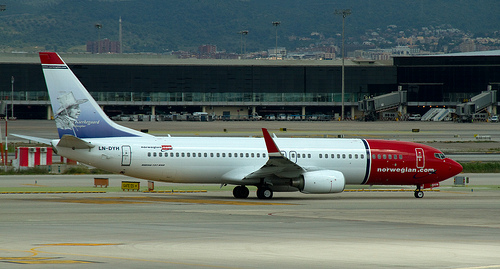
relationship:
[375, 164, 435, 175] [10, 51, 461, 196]
logo on plane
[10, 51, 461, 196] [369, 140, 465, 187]
plane has front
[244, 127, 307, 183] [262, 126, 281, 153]
wing has tip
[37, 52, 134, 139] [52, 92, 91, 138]
tip has portrait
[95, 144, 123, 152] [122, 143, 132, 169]
letters are next to door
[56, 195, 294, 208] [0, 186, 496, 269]
lines are painted on concrete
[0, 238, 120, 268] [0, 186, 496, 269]
lines are painted on concrete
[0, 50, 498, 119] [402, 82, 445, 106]
terminal has gates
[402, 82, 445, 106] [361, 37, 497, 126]
gates are in background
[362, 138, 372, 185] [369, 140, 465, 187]
stripe between front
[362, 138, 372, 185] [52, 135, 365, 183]
stripe between sections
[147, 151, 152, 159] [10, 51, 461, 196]
window on plane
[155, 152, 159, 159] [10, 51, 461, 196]
window on plane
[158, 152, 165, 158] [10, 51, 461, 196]
window on plane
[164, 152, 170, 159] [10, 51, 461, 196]
window on plane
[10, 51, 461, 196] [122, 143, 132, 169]
plane has door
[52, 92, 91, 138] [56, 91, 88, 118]
woman has hat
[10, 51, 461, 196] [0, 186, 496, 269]
plane sitting o runway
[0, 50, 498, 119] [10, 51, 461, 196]
terminal behind plane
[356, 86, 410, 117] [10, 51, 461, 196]
jetway behind plane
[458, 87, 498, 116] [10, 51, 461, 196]
jetway behind plane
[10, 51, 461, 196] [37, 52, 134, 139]
plane has tail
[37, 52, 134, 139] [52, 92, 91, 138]
tail has portrait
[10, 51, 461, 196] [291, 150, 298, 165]
plane has door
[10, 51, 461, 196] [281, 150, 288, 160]
plane has door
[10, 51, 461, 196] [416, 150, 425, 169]
plane has door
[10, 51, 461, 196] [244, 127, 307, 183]
plane has wing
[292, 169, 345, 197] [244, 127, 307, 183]
engine beside wing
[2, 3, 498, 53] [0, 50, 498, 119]
hill behind terminal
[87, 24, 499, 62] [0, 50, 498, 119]
city behind terminal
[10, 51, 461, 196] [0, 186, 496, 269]
plane standing on concrete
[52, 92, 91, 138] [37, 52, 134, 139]
portrait painted on tip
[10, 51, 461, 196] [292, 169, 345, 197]
plane has engine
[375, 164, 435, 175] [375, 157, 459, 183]
logo wrote on side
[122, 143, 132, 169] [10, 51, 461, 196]
door on plane